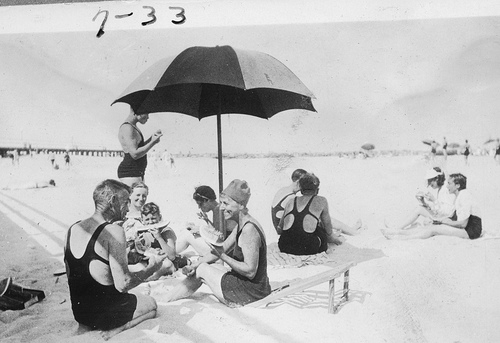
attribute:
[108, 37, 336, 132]
umbrella — open, color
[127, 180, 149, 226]
woman — smiling, eating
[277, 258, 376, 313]
bench — wooden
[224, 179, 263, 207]
cap — black, grey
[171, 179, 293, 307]
lady — light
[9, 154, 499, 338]
ground — bare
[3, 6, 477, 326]
picture — black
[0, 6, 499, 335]
scene — black